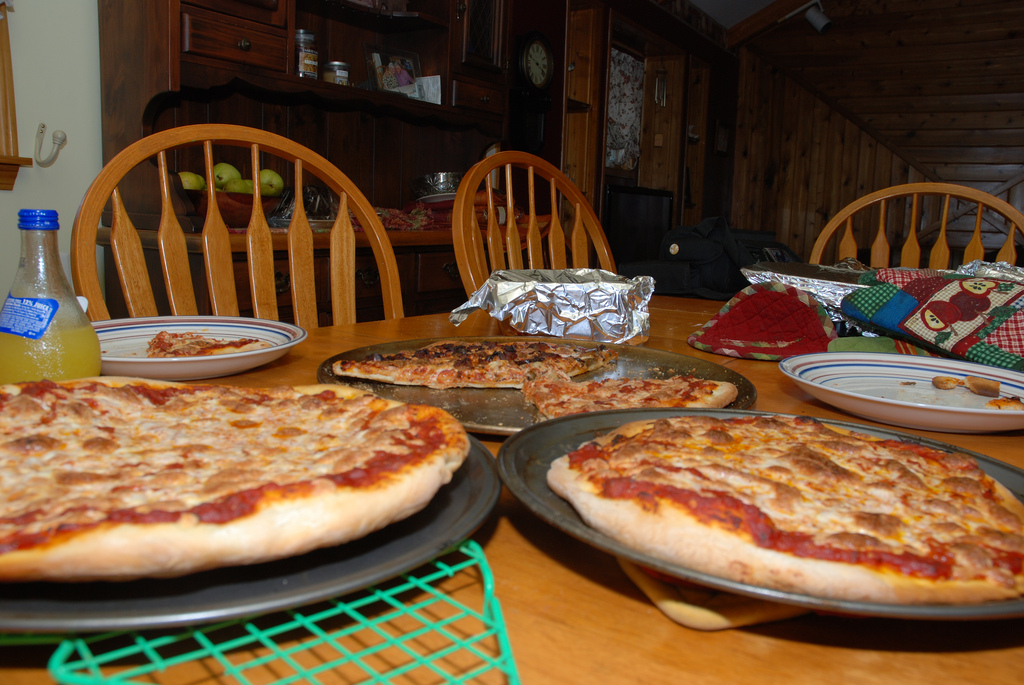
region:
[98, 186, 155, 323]
Slinder wooden slat on a chair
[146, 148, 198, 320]
Slinder wooden slat on a chair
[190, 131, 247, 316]
Slinder wooden slat on a chair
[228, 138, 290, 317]
Slinder wooden slat on a chair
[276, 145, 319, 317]
Slinder wooden slat on a chair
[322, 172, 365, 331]
Slinder wooden slat on a chair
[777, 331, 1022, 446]
Pizza crust on a plate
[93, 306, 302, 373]
Pizza on a plate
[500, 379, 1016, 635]
Large pizza in a pan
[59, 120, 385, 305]
the back of a chair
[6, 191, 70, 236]
the lid of a bottle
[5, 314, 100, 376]
liquid that is yellow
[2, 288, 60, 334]
a label that is blue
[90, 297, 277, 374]
a plate that is white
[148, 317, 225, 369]
a slice of pizza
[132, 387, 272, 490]
cheese on a pizza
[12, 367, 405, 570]
one whole serving of pizza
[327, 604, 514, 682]
a green metal cooling rack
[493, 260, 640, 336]
a bowl with tin foil on it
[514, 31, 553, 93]
clock on the wall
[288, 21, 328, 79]
jar on the cabinet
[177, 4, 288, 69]
drawer in the cabinet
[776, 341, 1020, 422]
red and blue stripes on the plate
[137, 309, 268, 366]
slice of pizza on the plate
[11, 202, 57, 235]
blue cap on the bottle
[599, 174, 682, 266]
Television in the back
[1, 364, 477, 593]
pizza on the pan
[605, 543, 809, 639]
hot pad under the pan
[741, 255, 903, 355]
metal foil on the container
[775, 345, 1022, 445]
plate on the table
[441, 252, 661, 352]
tin foil over the container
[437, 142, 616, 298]
chair at the table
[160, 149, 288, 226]
Bowl of fruit on the cabinet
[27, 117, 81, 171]
hook on the wall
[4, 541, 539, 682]
Green metal rack on the table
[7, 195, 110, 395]
bottle on the table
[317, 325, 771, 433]
metal pan on the table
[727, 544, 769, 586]
crust on the pizza is brown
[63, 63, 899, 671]
this is a dinner table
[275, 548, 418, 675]
the grate is green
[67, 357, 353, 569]
this is a pizza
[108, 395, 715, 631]
the pizzas are cooked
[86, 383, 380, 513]
the cheese is melted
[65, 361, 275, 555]
the cheese is white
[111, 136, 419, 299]
the chair is wooden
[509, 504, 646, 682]
the table is wood grain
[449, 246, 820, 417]
the bowl is covered in foil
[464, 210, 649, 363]
the foil is silver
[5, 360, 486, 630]
Pizza pie on the table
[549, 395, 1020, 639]
Pizza pie on the table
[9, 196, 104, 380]
Bottle of juice on the table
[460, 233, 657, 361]
aluminium foil on the table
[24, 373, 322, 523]
Cheese on the pizza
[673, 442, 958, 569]
Cheese on the pizza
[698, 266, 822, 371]
oven matt on the table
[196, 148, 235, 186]
apple in the bowl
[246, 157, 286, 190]
apple in the bowl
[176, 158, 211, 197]
apple in the bowl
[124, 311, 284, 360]
slice of pizza on plate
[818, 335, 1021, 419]
slice of pizza on plate